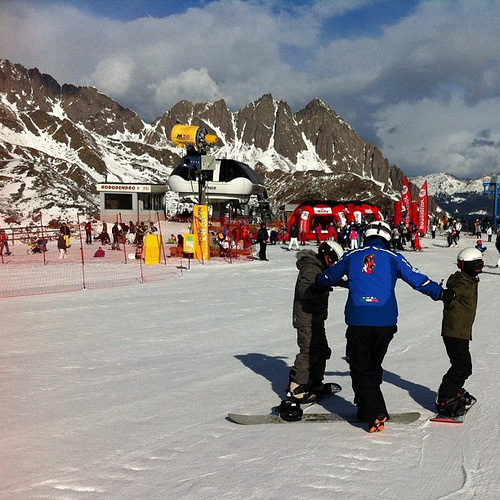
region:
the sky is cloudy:
[49, 27, 290, 139]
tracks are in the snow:
[93, 440, 260, 485]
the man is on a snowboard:
[205, 372, 497, 463]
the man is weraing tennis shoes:
[351, 402, 428, 453]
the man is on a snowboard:
[423, 373, 498, 462]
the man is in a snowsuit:
[277, 295, 387, 387]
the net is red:
[27, 209, 263, 390]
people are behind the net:
[40, 203, 226, 388]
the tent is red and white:
[288, 175, 498, 339]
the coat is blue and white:
[334, 232, 496, 438]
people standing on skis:
[220, 211, 480, 441]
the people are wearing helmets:
[277, 210, 487, 287]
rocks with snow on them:
[196, 87, 371, 200]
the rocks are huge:
[221, 25, 343, 167]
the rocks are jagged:
[172, 69, 348, 166]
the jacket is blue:
[322, 245, 419, 345]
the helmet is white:
[328, 207, 417, 250]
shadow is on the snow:
[205, 325, 305, 417]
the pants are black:
[430, 327, 479, 408]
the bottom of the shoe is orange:
[354, 400, 393, 437]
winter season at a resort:
[21, 11, 479, 481]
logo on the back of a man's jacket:
[356, 250, 376, 280]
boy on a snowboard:
[431, 235, 481, 431]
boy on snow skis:
[265, 232, 340, 423]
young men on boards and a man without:
[240, 215, 487, 441]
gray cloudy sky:
[361, 55, 491, 132]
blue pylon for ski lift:
[471, 170, 496, 240]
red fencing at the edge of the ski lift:
[0, 227, 252, 284]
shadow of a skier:
[230, 335, 290, 385]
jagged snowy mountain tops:
[175, 77, 351, 122]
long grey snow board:
[220, 399, 425, 430]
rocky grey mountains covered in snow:
[2, 54, 498, 256]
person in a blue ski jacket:
[313, 213, 453, 442]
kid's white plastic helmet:
[454, 244, 489, 281]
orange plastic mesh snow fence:
[0, 211, 261, 304]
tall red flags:
[393, 165, 437, 245]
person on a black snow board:
[265, 234, 347, 419]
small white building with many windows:
[91, 174, 176, 226]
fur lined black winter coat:
[289, 247, 336, 327]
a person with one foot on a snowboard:
[213, 216, 458, 462]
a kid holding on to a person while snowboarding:
[280, 225, 350, 425]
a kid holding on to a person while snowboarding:
[428, 233, 485, 440]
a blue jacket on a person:
[307, 227, 451, 348]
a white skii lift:
[159, 144, 269, 203]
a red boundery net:
[1, 204, 263, 304]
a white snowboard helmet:
[321, 238, 351, 269]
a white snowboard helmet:
[455, 237, 482, 272]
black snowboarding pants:
[439, 317, 474, 422]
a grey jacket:
[286, 236, 338, 342]